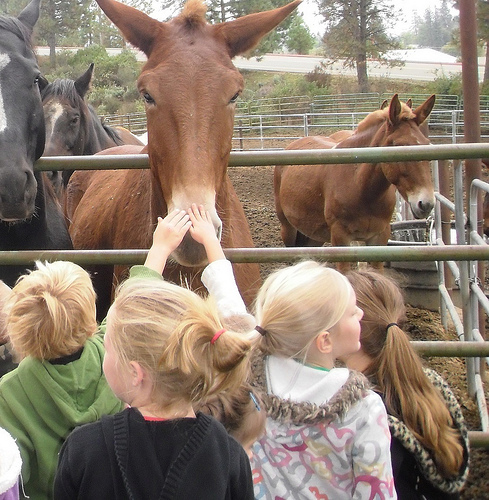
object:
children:
[0, 204, 471, 500]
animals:
[0, 0, 437, 311]